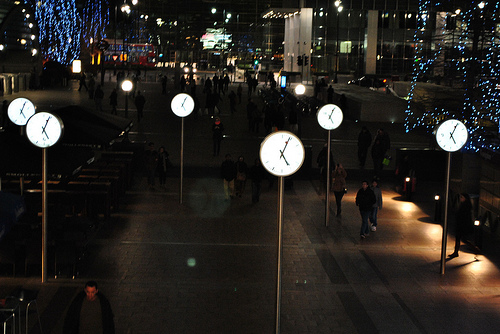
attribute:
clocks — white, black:
[6, 96, 39, 131]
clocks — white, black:
[22, 111, 66, 155]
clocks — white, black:
[168, 90, 196, 121]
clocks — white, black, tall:
[254, 129, 306, 182]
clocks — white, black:
[312, 101, 345, 136]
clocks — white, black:
[433, 116, 469, 159]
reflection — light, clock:
[184, 173, 235, 222]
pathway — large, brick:
[26, 155, 429, 333]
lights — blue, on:
[397, 2, 499, 155]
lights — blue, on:
[79, 2, 115, 50]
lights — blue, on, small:
[32, 1, 85, 73]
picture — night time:
[0, 1, 499, 334]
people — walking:
[350, 179, 380, 242]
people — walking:
[369, 179, 388, 232]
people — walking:
[217, 149, 241, 205]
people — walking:
[230, 153, 253, 209]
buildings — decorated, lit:
[259, 3, 484, 98]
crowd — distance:
[76, 65, 264, 124]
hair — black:
[359, 180, 370, 189]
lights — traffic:
[293, 52, 312, 69]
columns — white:
[297, 7, 316, 79]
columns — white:
[290, 15, 300, 81]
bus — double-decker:
[98, 38, 163, 75]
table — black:
[17, 190, 114, 223]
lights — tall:
[117, 3, 133, 18]